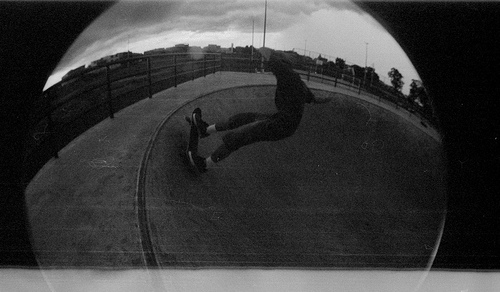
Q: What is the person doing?
A: Skateboarding.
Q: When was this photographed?
A: Daytime.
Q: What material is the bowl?
A: Cement.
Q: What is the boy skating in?
A: A bowl.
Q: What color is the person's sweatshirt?
A: Black.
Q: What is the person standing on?
A: Skateboard.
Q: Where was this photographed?
A: Skate park.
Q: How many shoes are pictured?
A: Two.